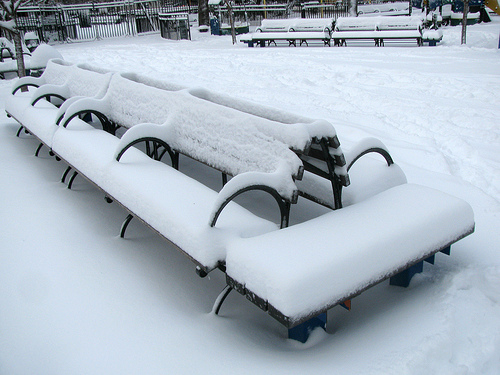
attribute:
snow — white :
[222, 180, 478, 313]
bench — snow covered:
[0, 59, 476, 346]